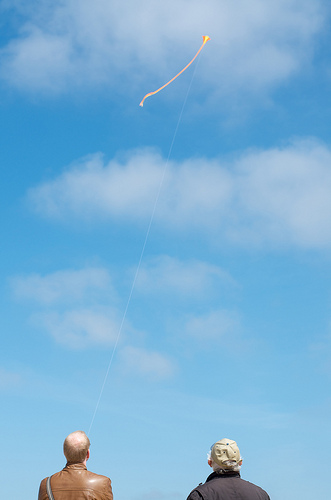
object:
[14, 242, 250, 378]
clouds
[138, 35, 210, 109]
kite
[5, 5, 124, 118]
air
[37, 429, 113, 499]
man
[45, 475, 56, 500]
strap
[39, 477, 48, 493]
shoulder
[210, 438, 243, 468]
hat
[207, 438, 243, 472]
head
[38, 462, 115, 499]
coat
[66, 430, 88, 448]
balding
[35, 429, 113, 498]
gentleman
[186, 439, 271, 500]
man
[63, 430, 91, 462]
hair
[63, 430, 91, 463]
head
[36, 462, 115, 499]
jacket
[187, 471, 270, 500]
jacket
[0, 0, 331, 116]
sky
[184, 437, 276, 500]
gentleman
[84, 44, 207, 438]
string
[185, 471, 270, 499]
coat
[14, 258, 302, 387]
sky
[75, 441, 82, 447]
bald spot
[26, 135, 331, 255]
clouds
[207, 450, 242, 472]
hair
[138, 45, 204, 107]
tail